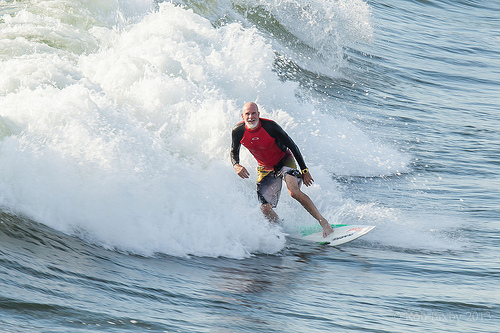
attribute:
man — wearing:
[223, 85, 351, 264]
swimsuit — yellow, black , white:
[251, 162, 304, 217]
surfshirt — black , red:
[231, 127, 314, 182]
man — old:
[229, 100, 332, 236]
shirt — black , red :
[230, 116, 306, 171]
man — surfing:
[230, 97, 295, 170]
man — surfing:
[227, 101, 337, 255]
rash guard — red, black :
[220, 118, 309, 179]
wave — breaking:
[14, 5, 391, 251]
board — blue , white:
[289, 220, 378, 247]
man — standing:
[208, 108, 355, 255]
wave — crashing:
[2, 2, 416, 261]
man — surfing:
[232, 99, 329, 256]